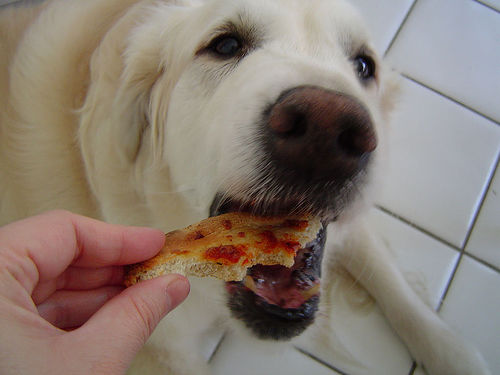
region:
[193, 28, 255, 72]
Dog has dark eye.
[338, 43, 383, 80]
Dog has dark eye.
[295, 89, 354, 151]
Dog has black and brown nose.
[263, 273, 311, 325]
Dog has pink tongue.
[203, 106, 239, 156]
Dog has white face.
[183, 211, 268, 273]
Dog is eating pizza crust.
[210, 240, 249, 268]
Red sauce on pizza.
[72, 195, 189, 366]
Person holding pizza crust in left hand.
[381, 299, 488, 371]
Dog has white paw.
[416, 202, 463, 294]
White tiles on floor in room.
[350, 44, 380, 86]
White dogs right eye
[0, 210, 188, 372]
A hand holding food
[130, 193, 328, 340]
Fingers Putting pizza in dogs mouth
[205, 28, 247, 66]
The dogs left eye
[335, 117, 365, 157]
The dogs right nostril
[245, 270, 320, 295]
Two yellow bottom teeth in the dogs mouth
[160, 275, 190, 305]
Thumb nail on a persons hand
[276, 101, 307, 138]
The dogs left nostril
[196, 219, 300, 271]
Pizza sauce on the pizza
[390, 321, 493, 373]
Dogs white front leg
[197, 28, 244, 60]
Dog has dark eye.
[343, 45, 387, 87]
Dog has dark eye.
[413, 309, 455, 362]
Dog has white paw.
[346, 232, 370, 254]
Dog has white leg.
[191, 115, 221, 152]
Dog has white cheek.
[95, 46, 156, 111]
Dog has white ear.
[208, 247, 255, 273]
Red sauce on pizza crust.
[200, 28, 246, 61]
a dog's eye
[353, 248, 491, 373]
a dog's foot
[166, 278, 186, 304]
part of a finger nail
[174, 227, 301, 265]
part of a pizza slice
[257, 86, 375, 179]
nose of a dog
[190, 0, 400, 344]
a dog eating a slice of a pizza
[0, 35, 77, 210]
part of dog's white fur.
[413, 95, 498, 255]
part of a ceramic white tile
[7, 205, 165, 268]
index of a hand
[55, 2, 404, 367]
A hand feeding a dog pizza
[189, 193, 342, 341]
Pizza going into a dog's mouth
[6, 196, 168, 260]
Human index finger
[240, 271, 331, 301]
Teeth inside a dog's mouth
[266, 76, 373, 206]
Two dog nostrils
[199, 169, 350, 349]
Open mouth of a dog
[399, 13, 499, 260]
White floor tiels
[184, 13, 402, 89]
Two black eyes on a white dog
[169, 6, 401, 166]
Eyes and nose on a dog's face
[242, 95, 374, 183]
the nose of a dog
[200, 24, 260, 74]
the left eye of a dog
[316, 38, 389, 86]
the right eye of a dog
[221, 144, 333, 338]
the mouth of a dog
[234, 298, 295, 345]
the lips of a dog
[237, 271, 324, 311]
the teeth of a dog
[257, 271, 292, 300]
the gums of a dog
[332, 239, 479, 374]
the leg of a dog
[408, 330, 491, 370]
the paw of a dog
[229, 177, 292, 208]
the wiskers of a dog